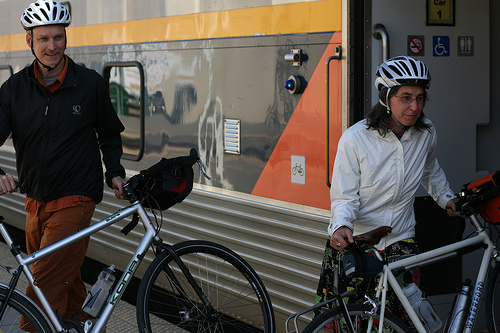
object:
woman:
[326, 55, 463, 333]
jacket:
[0, 56, 126, 205]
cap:
[374, 55, 431, 91]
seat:
[344, 225, 393, 245]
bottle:
[80, 264, 117, 319]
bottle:
[400, 282, 445, 333]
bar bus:
[324, 53, 342, 188]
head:
[381, 63, 429, 126]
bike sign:
[292, 163, 305, 177]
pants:
[18, 196, 98, 331]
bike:
[283, 170, 500, 333]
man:
[0, 0, 128, 333]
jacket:
[326, 115, 460, 250]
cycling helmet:
[20, 0, 72, 30]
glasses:
[400, 95, 424, 103]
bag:
[123, 155, 200, 211]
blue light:
[284, 80, 294, 90]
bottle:
[443, 278, 474, 333]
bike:
[0, 147, 278, 333]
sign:
[407, 35, 425, 56]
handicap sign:
[432, 35, 450, 57]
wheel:
[134, 240, 279, 333]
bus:
[0, 0, 500, 333]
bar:
[378, 26, 389, 60]